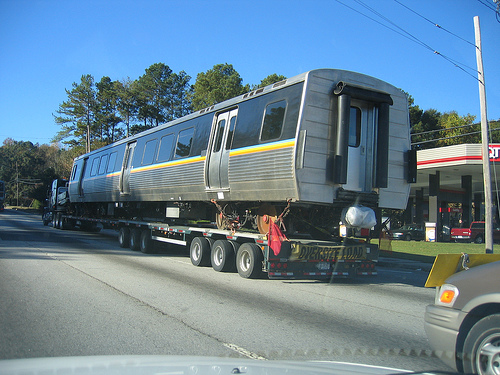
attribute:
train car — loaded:
[55, 67, 422, 218]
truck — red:
[449, 219, 499, 244]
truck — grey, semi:
[40, 67, 419, 284]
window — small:
[226, 101, 337, 158]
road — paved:
[0, 208, 455, 374]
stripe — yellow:
[137, 153, 220, 179]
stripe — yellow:
[228, 139, 303, 160]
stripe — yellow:
[419, 153, 482, 172]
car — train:
[32, 58, 430, 286]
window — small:
[91, 155, 100, 177]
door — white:
[328, 81, 395, 207]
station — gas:
[418, 130, 478, 248]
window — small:
[323, 92, 369, 157]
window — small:
[256, 102, 296, 159]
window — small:
[227, 112, 245, 161]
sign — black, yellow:
[291, 236, 387, 268]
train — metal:
[64, 73, 414, 233]